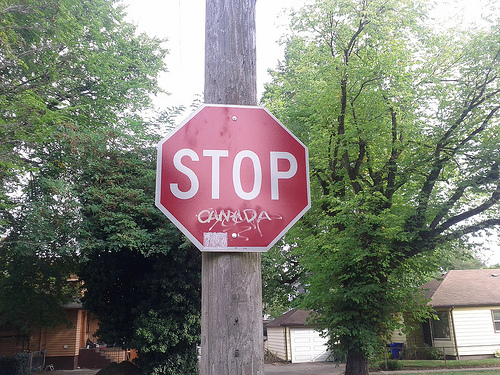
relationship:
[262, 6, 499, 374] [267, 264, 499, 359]
tree in front of house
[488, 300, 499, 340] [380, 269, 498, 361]
window on house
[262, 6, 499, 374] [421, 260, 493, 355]
tree in front of house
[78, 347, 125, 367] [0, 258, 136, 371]
steps leading to house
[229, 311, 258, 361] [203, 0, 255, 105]
lines in pole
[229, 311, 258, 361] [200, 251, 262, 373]
lines in pole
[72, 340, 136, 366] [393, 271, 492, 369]
small wall on side of house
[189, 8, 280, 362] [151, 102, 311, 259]
wooden post holding sign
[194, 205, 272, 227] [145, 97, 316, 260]
cananda written on stop sign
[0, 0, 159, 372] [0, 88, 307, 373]
tree next to tree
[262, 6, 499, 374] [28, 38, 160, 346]
tree next to tree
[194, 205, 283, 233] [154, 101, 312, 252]
words on stop sign